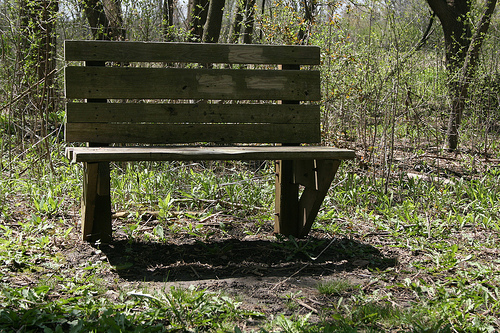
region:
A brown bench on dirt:
[41, 36, 351, 243]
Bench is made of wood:
[51, 27, 366, 245]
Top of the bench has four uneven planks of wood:
[53, 29, 343, 150]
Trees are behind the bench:
[55, 0, 477, 166]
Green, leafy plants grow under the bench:
[10, 151, 484, 326]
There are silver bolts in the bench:
[267, 160, 300, 240]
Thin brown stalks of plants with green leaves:
[305, 25, 496, 205]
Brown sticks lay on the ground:
[248, 229, 338, 304]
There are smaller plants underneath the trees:
[361, 0, 486, 178]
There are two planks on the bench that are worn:
[186, 44, 310, 109]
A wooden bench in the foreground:
[42, 35, 360, 242]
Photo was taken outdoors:
[1, 1, 491, 321]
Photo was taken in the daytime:
[1, 2, 488, 324]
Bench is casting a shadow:
[88, 209, 412, 290]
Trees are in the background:
[2, 2, 492, 157]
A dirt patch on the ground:
[141, 236, 333, 298]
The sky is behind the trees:
[44, 2, 372, 26]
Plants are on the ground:
[23, 293, 465, 331]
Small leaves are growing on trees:
[6, 8, 496, 123]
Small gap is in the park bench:
[63, 53, 321, 74]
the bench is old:
[61, 41, 322, 226]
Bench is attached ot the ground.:
[73, 48, 333, 266]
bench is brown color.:
[78, 66, 323, 210]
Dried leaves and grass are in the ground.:
[6, 137, 488, 324]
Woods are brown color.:
[20, 8, 492, 45]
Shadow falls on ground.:
[64, 45, 424, 298]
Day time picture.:
[12, 8, 496, 308]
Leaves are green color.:
[3, 24, 68, 179]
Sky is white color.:
[49, 1, 194, 23]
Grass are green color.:
[12, 290, 192, 328]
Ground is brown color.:
[78, 242, 320, 309]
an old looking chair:
[44, 46, 439, 304]